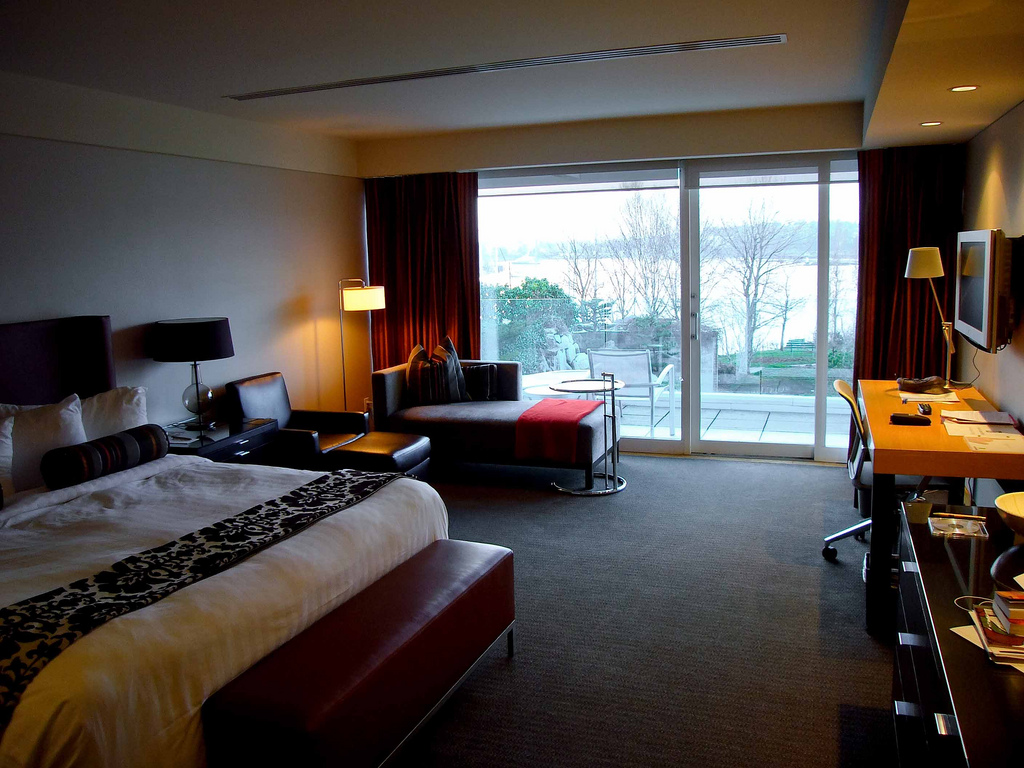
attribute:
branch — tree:
[562, 238, 595, 303]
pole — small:
[359, 313, 388, 413]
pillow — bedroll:
[20, 406, 183, 502]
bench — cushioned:
[192, 525, 542, 755]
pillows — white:
[9, 375, 157, 460]